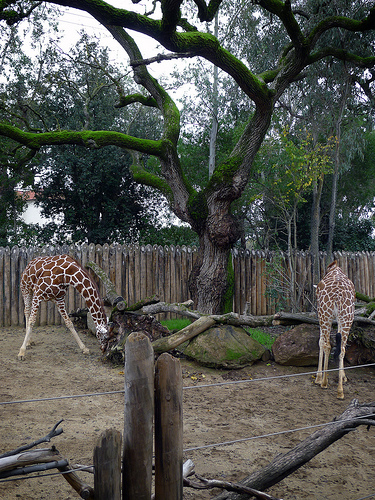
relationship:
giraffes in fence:
[8, 252, 356, 412] [3, 237, 374, 329]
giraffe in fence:
[14, 251, 114, 362] [1, 325, 374, 498]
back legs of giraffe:
[18, 267, 35, 349] [14, 251, 114, 362]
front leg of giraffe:
[317, 326, 329, 386] [313, 258, 355, 397]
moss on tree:
[35, 130, 163, 152] [0, 0, 374, 326]